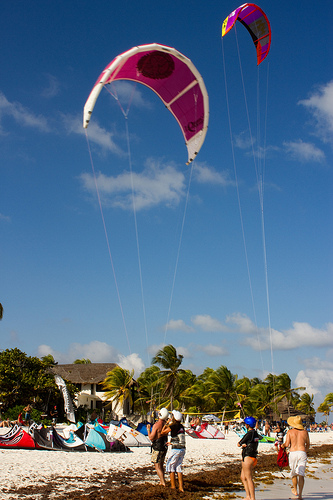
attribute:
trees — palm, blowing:
[100, 343, 317, 423]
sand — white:
[1, 429, 332, 498]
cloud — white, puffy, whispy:
[77, 157, 185, 213]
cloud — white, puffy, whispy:
[196, 162, 230, 189]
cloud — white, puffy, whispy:
[284, 139, 322, 162]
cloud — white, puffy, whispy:
[298, 79, 332, 140]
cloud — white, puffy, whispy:
[66, 106, 127, 156]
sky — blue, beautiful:
[1, 0, 332, 422]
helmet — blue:
[244, 413, 255, 428]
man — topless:
[278, 412, 313, 499]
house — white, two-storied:
[52, 361, 132, 421]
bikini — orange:
[249, 454, 261, 468]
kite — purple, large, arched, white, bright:
[83, 39, 211, 166]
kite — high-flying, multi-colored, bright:
[220, 0, 273, 67]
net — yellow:
[163, 407, 247, 426]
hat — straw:
[284, 410, 315, 431]